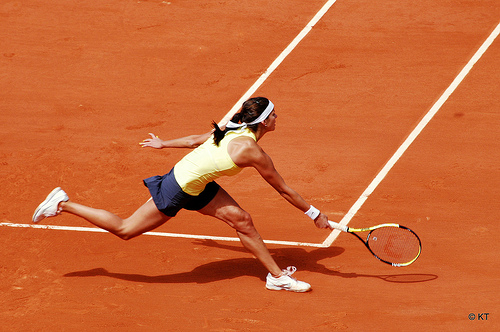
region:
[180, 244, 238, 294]
shadow on the tennis court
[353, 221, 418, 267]
a tennis racket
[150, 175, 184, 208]
a blue skirt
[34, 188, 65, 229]
a white shoe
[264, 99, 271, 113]
a white headband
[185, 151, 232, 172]
a yellow tank top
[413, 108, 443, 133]
a white line on the court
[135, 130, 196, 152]
the womens arm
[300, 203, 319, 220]
a sweat band on the arm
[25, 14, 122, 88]
the tennis court is brown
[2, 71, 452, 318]
tennis player on the court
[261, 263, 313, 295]
shoe of the player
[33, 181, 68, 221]
shoe of the player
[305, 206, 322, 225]
wrist band of the player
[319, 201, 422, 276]
tennis racquet in hand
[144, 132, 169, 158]
hand of the player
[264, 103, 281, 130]
headband on the player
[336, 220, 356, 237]
grip on the racquet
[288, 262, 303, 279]
laces on the shoe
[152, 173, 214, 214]
skirt on the player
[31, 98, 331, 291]
a female tennis player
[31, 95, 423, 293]
a tennis player swinging racket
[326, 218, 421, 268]
a white yellow and black racket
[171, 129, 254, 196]
a yellow tank top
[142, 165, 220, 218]
a blue tennis skirt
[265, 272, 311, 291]
a white tennis shoe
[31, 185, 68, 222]
a white tennis shoe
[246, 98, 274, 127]
a white head band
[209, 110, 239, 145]
a woman's pony tail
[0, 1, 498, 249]
a tennis court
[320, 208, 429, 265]
The tennis racket in the player's hand.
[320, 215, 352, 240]
The handle of the tennis racket.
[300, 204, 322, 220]
The sweatband on the player's wrist.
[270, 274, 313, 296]
The right sneaker the player is wearing.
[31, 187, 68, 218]
The left sneaker the player is wearing.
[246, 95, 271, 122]
The white headband on the player's head.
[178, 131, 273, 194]
The yellow shirt the player is wearing.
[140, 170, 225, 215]
The blue skirt/shorts the player is wearing.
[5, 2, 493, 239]
The white boundary lines on the court.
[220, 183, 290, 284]
The right leg of the player.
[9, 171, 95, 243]
White and black shoe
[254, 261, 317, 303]
White and black shoe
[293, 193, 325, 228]
White and black swet band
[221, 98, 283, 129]
White and black swet band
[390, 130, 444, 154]
Part of a white line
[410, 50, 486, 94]
Part of a white line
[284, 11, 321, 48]
Part of a white line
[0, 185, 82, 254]
Part of a white line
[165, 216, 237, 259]
Part of a white line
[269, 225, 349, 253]
Part of a white line